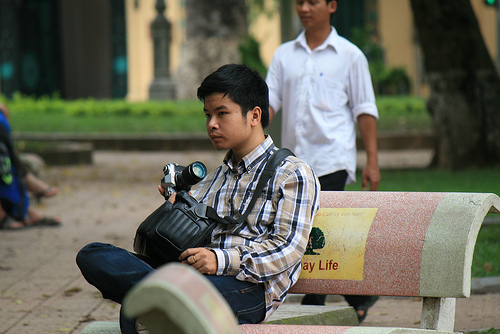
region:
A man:
[136, 97, 299, 331]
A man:
[177, 111, 270, 308]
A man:
[160, 103, 235, 294]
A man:
[147, 154, 209, 256]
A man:
[219, 159, 310, 333]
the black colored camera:
[161, 154, 213, 199]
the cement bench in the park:
[357, 175, 467, 330]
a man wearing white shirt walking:
[270, 0, 392, 186]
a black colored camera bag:
[131, 153, 293, 260]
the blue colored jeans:
[70, 234, 284, 317]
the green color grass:
[49, 94, 149, 133]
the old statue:
[142, 3, 180, 108]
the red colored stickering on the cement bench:
[371, 185, 446, 291]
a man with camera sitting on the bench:
[133, 43, 313, 325]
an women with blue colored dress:
[3, 164, 63, 239]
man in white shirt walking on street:
[271, 1, 389, 187]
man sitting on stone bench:
[197, 66, 497, 323]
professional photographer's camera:
[155, 157, 211, 192]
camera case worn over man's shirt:
[128, 178, 298, 263]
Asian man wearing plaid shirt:
[176, 61, 331, 325]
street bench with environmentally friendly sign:
[291, 183, 496, 303]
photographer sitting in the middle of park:
[6, 61, 386, 333]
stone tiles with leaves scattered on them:
[2, 238, 79, 333]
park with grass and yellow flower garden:
[1, 7, 210, 161]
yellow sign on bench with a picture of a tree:
[303, 185, 381, 296]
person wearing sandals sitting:
[5, 97, 90, 250]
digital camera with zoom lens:
[153, 150, 217, 210]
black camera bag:
[122, 176, 217, 263]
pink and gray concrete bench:
[94, 162, 496, 332]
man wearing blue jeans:
[58, 48, 340, 332]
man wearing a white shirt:
[259, 0, 406, 224]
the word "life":
[313, 249, 350, 284]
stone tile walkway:
[21, 172, 114, 327]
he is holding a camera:
[60, 49, 322, 316]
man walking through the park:
[247, 3, 373, 276]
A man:
[165, 179, 254, 321]